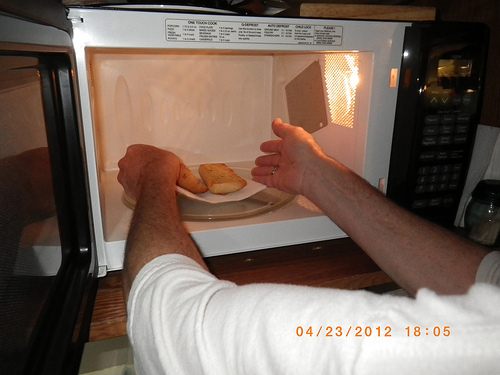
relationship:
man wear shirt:
[115, 117, 498, 374] [150, 245, 418, 372]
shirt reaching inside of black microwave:
[150, 245, 418, 372] [0, 5, 483, 375]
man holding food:
[117, 117, 499, 374] [139, 134, 292, 213]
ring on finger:
[272, 166, 279, 175] [265, 142, 283, 149]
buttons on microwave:
[413, 83, 473, 196] [62, 4, 486, 267]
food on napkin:
[178, 161, 250, 198] [175, 175, 268, 205]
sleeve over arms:
[126, 252, 500, 374] [115, 116, 492, 293]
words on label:
[167, 20, 341, 44] [168, 15, 346, 49]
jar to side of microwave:
[465, 176, 497, 245] [1, 12, 488, 373]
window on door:
[0, 65, 64, 373] [0, 16, 105, 365]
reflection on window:
[1, 148, 56, 252] [0, 65, 64, 373]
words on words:
[165, 18, 343, 48] [167, 20, 341, 44]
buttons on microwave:
[413, 83, 473, 196] [33, 3, 483, 229]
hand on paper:
[247, 116, 317, 193] [174, 154, 271, 204]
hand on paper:
[119, 143, 181, 185] [174, 154, 271, 204]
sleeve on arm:
[118, 253, 498, 373] [108, 132, 224, 308]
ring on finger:
[268, 163, 280, 177] [201, 111, 323, 171]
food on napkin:
[178, 163, 247, 194] [175, 179, 268, 204]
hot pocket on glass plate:
[198, 162, 248, 194] [123, 167, 298, 220]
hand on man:
[117, 144, 181, 202] [117, 117, 499, 374]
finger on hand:
[267, 116, 296, 139] [249, 118, 321, 192]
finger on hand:
[251, 153, 283, 167] [254, 110, 326, 202]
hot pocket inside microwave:
[198, 163, 247, 195] [2, 5, 411, 274]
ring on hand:
[272, 166, 279, 175] [250, 111, 481, 294]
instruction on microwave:
[160, 15, 347, 50] [2, 5, 411, 274]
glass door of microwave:
[5, 77, 100, 319] [25, 32, 491, 269]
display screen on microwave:
[434, 48, 484, 80] [1, 12, 488, 373]